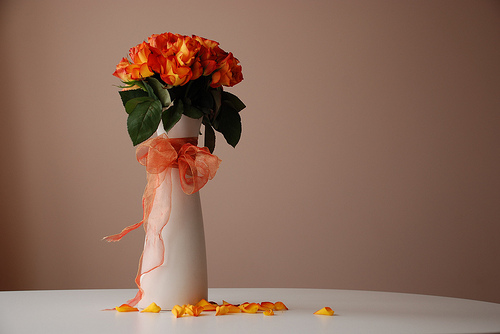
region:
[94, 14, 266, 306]
vase with orange flowers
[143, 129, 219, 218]
ribbon on the vase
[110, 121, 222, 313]
vase on the table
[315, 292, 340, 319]
petal on the table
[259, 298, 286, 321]
petals on the table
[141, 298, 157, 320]
petal on the table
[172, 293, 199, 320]
petals on the table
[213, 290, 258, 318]
petals on the table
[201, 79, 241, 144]
leaves in the vase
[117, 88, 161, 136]
leaves in the vase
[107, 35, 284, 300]
beautiful orange rose flowers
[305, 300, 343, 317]
A yellow rose petal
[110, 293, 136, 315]
A yellow rose petal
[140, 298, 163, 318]
A yellow rose petal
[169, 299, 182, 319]
A yellow rose petal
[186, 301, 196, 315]
A yellow rose petal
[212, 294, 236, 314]
A yellow rose petal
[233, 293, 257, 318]
A yellow rose petal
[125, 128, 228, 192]
An orange flower ribbon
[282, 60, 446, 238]
A pink wall surface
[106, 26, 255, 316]
a floral arrangement is on a table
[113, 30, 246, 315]
the flowers are is a white vase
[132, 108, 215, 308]
an orange ribbon is tied around the vase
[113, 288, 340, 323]
flower petals are on the table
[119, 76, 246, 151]
green leaves are under the flowers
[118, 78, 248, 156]
the leaves are from a rose bush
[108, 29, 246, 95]
the roses are yellow buds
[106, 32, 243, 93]
the roses are orange tipped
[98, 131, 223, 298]
the bow is orange organza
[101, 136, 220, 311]
the organza has wire in the sides of the fabric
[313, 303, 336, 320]
yellow and orange petal of a rose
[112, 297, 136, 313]
yellow and orange petal of a rose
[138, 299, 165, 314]
yellow and orange petal of a rose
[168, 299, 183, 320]
yellow and orange petal of a rose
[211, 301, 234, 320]
yellow and orange petal of a rose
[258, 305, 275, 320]
yellow and orange petal of a rose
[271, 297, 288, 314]
yellow and orange petal of a rose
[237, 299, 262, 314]
yellow and orange petal of a rose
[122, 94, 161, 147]
dark green leaf of a rose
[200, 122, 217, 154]
dark green leaf of a rose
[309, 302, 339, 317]
yellow and red rose petal on white table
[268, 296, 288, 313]
yellow and red rose petal on white table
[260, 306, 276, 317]
yellow and red rose petal on white table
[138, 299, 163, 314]
yellow and red rose petal on white table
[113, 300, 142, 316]
yellow and red rose petal on white table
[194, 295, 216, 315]
yellow and red rose petal on white table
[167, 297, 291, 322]
group of yellow and red rose petals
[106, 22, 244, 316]
yellow and red roses in a vase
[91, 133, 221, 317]
pink bowtie made of lace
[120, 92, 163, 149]
shiny green leaf of a rose